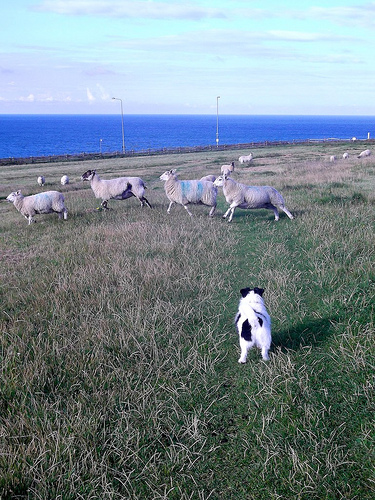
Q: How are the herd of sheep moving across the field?
A: Walking.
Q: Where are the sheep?
A: A grassy field.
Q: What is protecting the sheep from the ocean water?
A: Fence.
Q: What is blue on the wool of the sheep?
A: Dye.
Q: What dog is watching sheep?
A: Border collie.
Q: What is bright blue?
A: Ocean water.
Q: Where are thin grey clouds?
A: Sky.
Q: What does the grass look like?
A: Dry and brown.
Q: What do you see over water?
A: Horizon.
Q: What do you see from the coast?
A: Water.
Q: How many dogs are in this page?
A: One.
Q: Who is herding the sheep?
A: The dog.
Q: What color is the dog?
A: Black and white.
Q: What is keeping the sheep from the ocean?
A: The fence.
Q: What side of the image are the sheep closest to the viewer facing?
A: Left.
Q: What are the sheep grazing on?
A: Grass.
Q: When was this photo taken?
A: During the day.